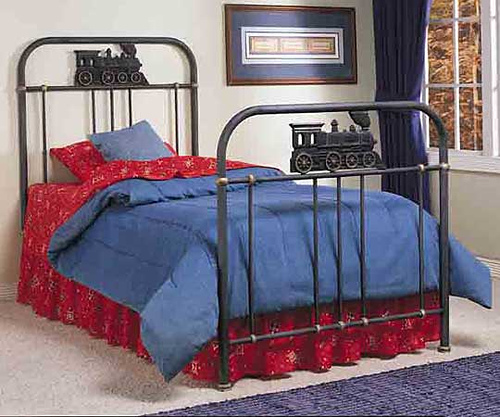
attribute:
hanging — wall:
[225, 7, 365, 91]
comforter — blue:
[92, 165, 211, 299]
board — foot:
[223, 102, 452, 358]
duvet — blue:
[39, 164, 488, 385]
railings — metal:
[210, 94, 459, 394]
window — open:
[370, 2, 499, 174]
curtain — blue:
[366, 5, 438, 194]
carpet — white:
[13, 344, 145, 414]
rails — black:
[204, 85, 464, 388]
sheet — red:
[17, 182, 80, 252]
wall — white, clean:
[4, 4, 216, 36]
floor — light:
[12, 351, 135, 414]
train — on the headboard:
[66, 40, 153, 86]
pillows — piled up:
[51, 120, 180, 180]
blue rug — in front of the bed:
[167, 362, 477, 412]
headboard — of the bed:
[16, 31, 202, 164]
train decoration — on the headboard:
[74, 40, 152, 88]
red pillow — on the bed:
[49, 136, 177, 178]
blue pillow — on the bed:
[86, 119, 174, 165]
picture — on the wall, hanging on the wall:
[221, 2, 359, 85]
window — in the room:
[420, 0, 483, 152]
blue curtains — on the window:
[416, 2, 484, 148]